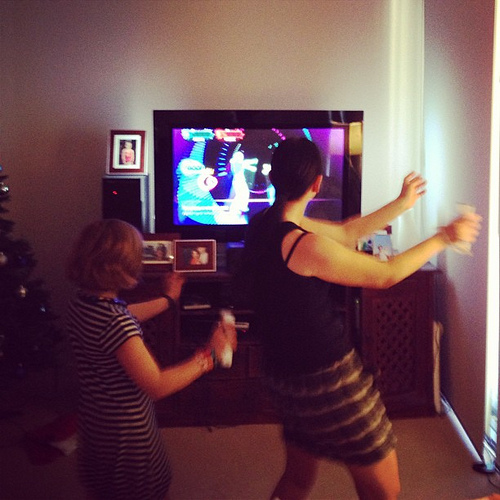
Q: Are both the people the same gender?
A: Yes, all the people are female.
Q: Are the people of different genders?
A: No, all the people are female.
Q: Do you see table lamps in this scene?
A: No, there are no table lamps.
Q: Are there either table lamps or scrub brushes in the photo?
A: No, there are no table lamps or scrub brushes.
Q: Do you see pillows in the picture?
A: No, there are no pillows.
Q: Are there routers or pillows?
A: No, there are no pillows or routers.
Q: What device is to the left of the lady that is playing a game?
A: The device is a controller.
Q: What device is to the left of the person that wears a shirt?
A: The device is a controller.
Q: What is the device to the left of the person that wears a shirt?
A: The device is a controller.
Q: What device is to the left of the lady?
A: The device is a controller.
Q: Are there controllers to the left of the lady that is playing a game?
A: Yes, there is a controller to the left of the lady.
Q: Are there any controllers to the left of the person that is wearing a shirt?
A: Yes, there is a controller to the left of the lady.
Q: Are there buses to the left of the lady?
A: No, there is a controller to the left of the lady.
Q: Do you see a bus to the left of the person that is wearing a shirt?
A: No, there is a controller to the left of the lady.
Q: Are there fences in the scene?
A: No, there are no fences.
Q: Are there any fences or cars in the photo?
A: No, there are no fences or cars.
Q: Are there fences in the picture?
A: No, there are no fences.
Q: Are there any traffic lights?
A: No, there are no traffic lights.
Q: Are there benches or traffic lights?
A: No, there are no traffic lights or benches.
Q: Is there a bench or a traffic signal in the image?
A: No, there are no traffic lights or benches.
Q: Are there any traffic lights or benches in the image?
A: No, there are no traffic lights or benches.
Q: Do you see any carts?
A: No, there are no carts.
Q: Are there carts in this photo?
A: No, there are no carts.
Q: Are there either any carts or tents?
A: No, there are no carts or tents.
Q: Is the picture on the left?
A: Yes, the picture is on the left of the image.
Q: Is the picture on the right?
A: No, the picture is on the left of the image.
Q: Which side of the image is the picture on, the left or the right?
A: The picture is on the left of the image.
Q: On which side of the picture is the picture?
A: The picture is on the left of the image.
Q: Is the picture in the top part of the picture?
A: Yes, the picture is in the top of the image.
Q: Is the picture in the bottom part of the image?
A: No, the picture is in the top of the image.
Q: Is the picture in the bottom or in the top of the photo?
A: The picture is in the top of the image.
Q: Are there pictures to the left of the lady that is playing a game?
A: Yes, there is a picture to the left of the lady.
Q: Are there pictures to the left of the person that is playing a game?
A: Yes, there is a picture to the left of the lady.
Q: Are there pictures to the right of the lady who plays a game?
A: No, the picture is to the left of the lady.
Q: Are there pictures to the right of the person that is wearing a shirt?
A: No, the picture is to the left of the lady.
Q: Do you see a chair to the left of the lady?
A: No, there is a picture to the left of the lady.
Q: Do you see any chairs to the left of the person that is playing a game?
A: No, there is a picture to the left of the lady.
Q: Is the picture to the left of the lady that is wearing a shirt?
A: Yes, the picture is to the left of the lady.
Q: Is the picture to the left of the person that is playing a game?
A: Yes, the picture is to the left of the lady.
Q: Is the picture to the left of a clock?
A: No, the picture is to the left of the lady.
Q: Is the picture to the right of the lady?
A: No, the picture is to the left of the lady.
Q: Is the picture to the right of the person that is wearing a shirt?
A: No, the picture is to the left of the lady.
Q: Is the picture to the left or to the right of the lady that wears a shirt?
A: The picture is to the left of the lady.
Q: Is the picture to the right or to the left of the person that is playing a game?
A: The picture is to the left of the lady.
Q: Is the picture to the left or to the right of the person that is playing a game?
A: The picture is to the left of the lady.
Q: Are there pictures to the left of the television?
A: Yes, there is a picture to the left of the television.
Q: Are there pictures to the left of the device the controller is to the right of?
A: Yes, there is a picture to the left of the television.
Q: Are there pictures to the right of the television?
A: No, the picture is to the left of the television.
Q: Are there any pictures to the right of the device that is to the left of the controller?
A: No, the picture is to the left of the television.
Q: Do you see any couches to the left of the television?
A: No, there is a picture to the left of the television.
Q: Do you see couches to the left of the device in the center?
A: No, there is a picture to the left of the television.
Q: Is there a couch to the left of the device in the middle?
A: No, there is a picture to the left of the television.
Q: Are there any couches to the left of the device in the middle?
A: No, there is a picture to the left of the television.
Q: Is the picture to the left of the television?
A: Yes, the picture is to the left of the television.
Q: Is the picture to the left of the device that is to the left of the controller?
A: Yes, the picture is to the left of the television.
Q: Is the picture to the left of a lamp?
A: No, the picture is to the left of the television.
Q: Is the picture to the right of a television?
A: No, the picture is to the left of a television.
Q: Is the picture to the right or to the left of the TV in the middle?
A: The picture is to the left of the television.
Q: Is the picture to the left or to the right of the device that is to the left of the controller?
A: The picture is to the left of the television.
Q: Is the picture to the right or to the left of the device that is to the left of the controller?
A: The picture is to the left of the television.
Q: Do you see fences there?
A: No, there are no fences.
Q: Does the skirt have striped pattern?
A: Yes, the skirt is striped.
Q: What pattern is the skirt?
A: The skirt is striped.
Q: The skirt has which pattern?
A: The skirt is striped.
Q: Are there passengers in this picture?
A: No, there are no passengers.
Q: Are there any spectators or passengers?
A: No, there are no passengers or spectators.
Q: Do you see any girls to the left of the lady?
A: Yes, there is a girl to the left of the lady.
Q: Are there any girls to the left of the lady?
A: Yes, there is a girl to the left of the lady.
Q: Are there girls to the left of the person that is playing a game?
A: Yes, there is a girl to the left of the lady.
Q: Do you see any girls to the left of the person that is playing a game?
A: Yes, there is a girl to the left of the lady.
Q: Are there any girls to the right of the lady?
A: No, the girl is to the left of the lady.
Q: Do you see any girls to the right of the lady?
A: No, the girl is to the left of the lady.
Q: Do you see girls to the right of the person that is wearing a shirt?
A: No, the girl is to the left of the lady.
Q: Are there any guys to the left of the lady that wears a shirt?
A: No, there is a girl to the left of the lady.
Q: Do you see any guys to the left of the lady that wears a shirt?
A: No, there is a girl to the left of the lady.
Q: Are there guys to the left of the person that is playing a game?
A: No, there is a girl to the left of the lady.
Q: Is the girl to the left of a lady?
A: Yes, the girl is to the left of a lady.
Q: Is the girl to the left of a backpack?
A: No, the girl is to the left of a lady.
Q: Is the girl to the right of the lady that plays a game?
A: No, the girl is to the left of the lady.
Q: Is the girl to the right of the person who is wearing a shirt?
A: No, the girl is to the left of the lady.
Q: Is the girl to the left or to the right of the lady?
A: The girl is to the left of the lady.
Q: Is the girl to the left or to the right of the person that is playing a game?
A: The girl is to the left of the lady.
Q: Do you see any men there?
A: No, there are no men.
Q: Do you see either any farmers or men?
A: No, there are no men or farmers.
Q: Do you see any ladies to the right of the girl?
A: Yes, there is a lady to the right of the girl.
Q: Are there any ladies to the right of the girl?
A: Yes, there is a lady to the right of the girl.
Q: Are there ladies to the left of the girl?
A: No, the lady is to the right of the girl.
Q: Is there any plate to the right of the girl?
A: No, there is a lady to the right of the girl.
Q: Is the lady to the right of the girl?
A: Yes, the lady is to the right of the girl.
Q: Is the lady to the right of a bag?
A: No, the lady is to the right of the girl.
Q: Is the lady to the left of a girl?
A: No, the lady is to the right of a girl.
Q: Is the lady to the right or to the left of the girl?
A: The lady is to the right of the girl.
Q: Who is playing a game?
A: The lady is playing a game.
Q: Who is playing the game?
A: The lady is playing a game.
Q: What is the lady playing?
A: The lady is playing a game.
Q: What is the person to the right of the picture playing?
A: The lady is playing a game.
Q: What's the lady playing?
A: The lady is playing a game.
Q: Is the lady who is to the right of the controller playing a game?
A: Yes, the lady is playing a game.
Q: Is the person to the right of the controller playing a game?
A: Yes, the lady is playing a game.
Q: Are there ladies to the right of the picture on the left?
A: Yes, there is a lady to the right of the picture.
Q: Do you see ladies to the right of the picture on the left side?
A: Yes, there is a lady to the right of the picture.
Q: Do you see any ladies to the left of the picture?
A: No, the lady is to the right of the picture.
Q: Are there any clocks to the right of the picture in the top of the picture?
A: No, there is a lady to the right of the picture.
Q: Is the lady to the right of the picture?
A: Yes, the lady is to the right of the picture.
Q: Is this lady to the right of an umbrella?
A: No, the lady is to the right of the picture.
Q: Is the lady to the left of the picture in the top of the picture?
A: No, the lady is to the right of the picture.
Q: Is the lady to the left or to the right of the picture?
A: The lady is to the right of the picture.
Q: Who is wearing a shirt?
A: The lady is wearing a shirt.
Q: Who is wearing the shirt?
A: The lady is wearing a shirt.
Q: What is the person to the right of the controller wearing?
A: The lady is wearing a shirt.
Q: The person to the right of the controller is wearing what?
A: The lady is wearing a shirt.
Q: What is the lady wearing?
A: The lady is wearing a shirt.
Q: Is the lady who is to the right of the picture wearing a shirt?
A: Yes, the lady is wearing a shirt.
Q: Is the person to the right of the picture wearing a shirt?
A: Yes, the lady is wearing a shirt.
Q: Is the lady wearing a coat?
A: No, the lady is wearing a shirt.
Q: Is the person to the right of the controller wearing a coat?
A: No, the lady is wearing a shirt.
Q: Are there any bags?
A: No, there are no bags.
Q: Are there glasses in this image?
A: No, there are no glasses.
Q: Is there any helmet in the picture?
A: No, there are no helmets.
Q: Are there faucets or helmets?
A: No, there are no helmets or faucets.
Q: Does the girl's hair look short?
A: Yes, the hair is short.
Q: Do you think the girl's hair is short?
A: Yes, the hair is short.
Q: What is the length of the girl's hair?
A: The hair is short.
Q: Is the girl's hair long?
A: No, the hair is short.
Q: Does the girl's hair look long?
A: No, the hair is short.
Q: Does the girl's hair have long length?
A: No, the hair is short.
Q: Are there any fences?
A: No, there are no fences.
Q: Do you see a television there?
A: Yes, there is a television.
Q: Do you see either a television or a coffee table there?
A: Yes, there is a television.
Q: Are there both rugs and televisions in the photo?
A: No, there is a television but no rugs.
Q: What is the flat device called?
A: The device is a television.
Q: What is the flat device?
A: The device is a television.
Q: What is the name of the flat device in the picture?
A: The device is a television.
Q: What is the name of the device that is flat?
A: The device is a television.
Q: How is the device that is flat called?
A: The device is a television.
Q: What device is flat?
A: The device is a television.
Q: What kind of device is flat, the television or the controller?
A: The television is flat.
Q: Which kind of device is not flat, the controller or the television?
A: The controller is not flat.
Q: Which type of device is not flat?
A: The device is a controller.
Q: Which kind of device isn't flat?
A: The device is a controller.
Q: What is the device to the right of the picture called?
A: The device is a television.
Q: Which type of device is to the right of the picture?
A: The device is a television.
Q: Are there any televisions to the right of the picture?
A: Yes, there is a television to the right of the picture.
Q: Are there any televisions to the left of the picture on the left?
A: No, the television is to the right of the picture.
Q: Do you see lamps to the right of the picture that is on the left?
A: No, there is a television to the right of the picture.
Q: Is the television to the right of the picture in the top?
A: Yes, the television is to the right of the picture.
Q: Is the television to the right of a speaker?
A: No, the television is to the right of the picture.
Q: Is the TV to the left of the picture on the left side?
A: No, the TV is to the right of the picture.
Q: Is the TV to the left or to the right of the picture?
A: The TV is to the right of the picture.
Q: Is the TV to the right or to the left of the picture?
A: The TV is to the right of the picture.